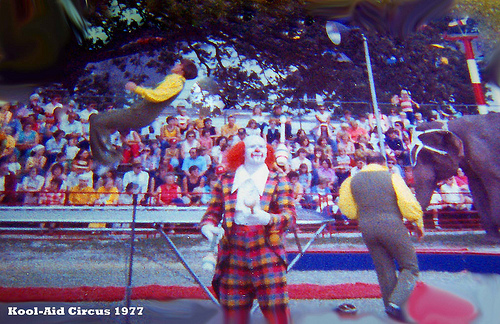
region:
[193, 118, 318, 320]
Clown in the circus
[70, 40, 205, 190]
Acrobat is jumping backward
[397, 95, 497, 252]
Elephant in the circus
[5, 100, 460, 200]
Viewers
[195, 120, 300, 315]
Clown has red hair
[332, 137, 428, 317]
Man wearing yellow long sleeve t-shirt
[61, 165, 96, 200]
Person wearing a yellow jacket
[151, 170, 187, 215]
Woman wearing a red top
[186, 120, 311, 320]
Clown wears squared cloths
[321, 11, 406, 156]
Light pole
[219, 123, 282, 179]
A male clown.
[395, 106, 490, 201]
A circus elephant.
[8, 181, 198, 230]
A trampoline.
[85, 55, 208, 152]
A man turning a flip.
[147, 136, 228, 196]
People watching the show.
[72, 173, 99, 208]
A man wearing yellow.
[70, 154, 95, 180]
A man wearing a hat.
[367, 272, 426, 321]
A man wearing a shoe.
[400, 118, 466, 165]
Elephant wearing something on it's head.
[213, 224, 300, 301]
A clown wearing plaid pants.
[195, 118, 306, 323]
Person dressed as a clown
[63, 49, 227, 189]
Person wearing grey and yellow clothing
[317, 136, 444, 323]
Person wearing grey and yellow clothing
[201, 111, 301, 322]
Person with face painted white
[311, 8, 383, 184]
Metal light fixture on top of a pole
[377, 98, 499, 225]
Large elephant wearing white decoration on its face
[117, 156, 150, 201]
Person wearing a white shirt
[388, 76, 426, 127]
Person wearing a red and white striped shirt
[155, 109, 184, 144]
Person wearing a yellow tank top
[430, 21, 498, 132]
Red and white striped pole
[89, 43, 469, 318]
entertainers at a circus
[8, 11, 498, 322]
the Kool-Aid Circus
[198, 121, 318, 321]
a clown with red hair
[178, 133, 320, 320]
a clown wearing a plaid outfit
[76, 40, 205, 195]
a man in yellow and grey doing a flip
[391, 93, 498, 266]
an elephant at a circus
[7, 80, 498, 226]
a crowd watches a circus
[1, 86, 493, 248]
spectators watch a show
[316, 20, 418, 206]
a light on a pole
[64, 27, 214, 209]
an acrobat at a circus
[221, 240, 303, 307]
the pants are checked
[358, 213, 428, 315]
his pants are grey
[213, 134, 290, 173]
the clown has red hair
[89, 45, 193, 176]
the man is in the air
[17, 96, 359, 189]
the people are spectators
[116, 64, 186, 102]
the man has a yellow shirt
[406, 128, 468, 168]
the elephant has white clothe on the face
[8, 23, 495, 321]
the picture was taken in 1977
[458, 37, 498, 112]
the post is red and white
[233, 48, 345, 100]
there are trees in the background